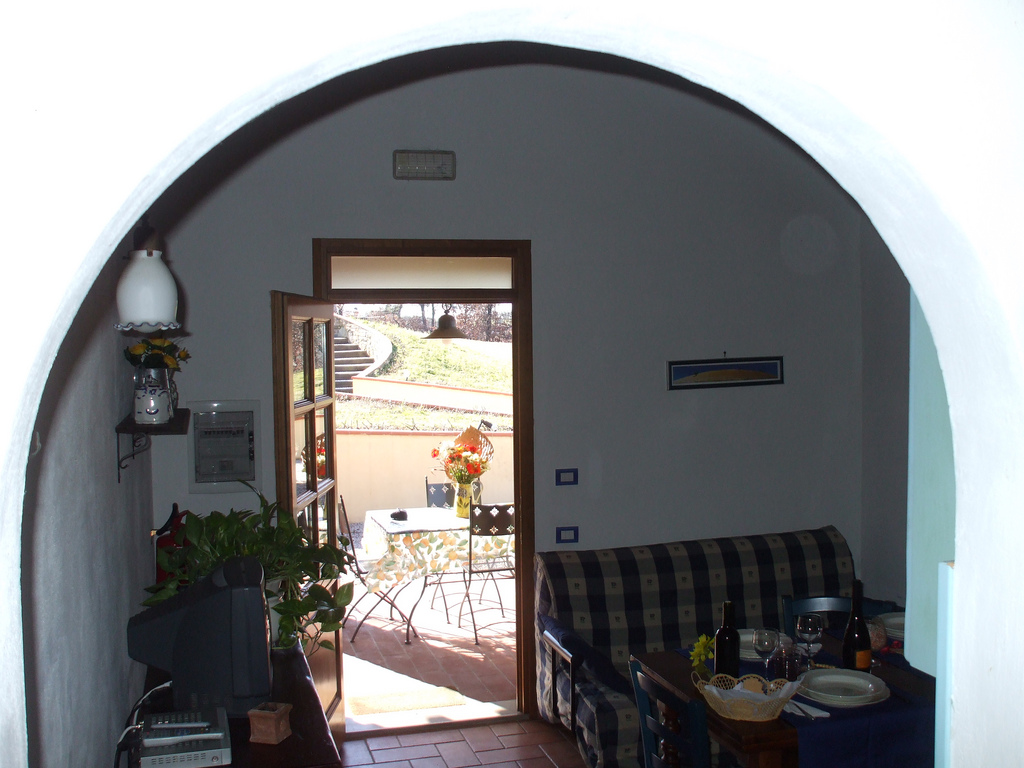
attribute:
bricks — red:
[307, 699, 565, 763]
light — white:
[112, 243, 176, 330]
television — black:
[175, 545, 311, 719]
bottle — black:
[696, 586, 741, 648]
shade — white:
[109, 237, 196, 322]